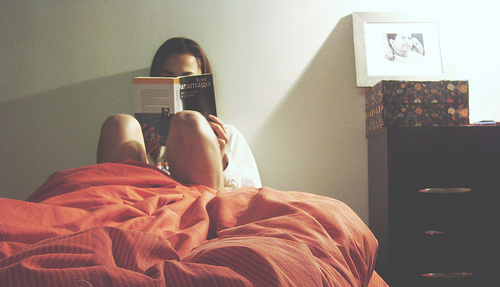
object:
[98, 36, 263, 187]
woman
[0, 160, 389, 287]
bed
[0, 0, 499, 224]
wall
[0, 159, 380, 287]
comforter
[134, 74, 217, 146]
book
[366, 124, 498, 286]
dresser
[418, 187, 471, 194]
handle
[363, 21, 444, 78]
picture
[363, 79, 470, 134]
box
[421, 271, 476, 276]
handle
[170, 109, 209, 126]
knees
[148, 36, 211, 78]
hair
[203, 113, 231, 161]
hands